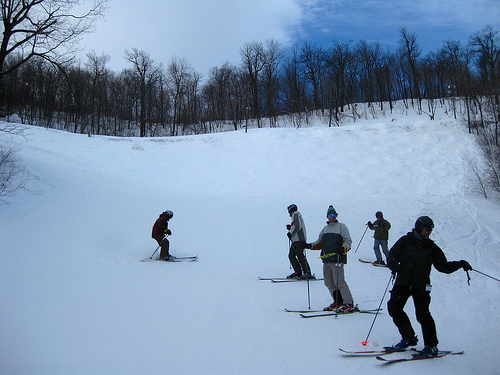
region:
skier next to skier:
[150, 209, 179, 262]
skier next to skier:
[284, 203, 311, 278]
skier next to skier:
[302, 205, 359, 315]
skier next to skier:
[368, 210, 393, 264]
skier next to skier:
[382, 214, 474, 355]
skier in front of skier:
[301, 202, 361, 316]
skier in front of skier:
[377, 215, 469, 357]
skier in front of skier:
[287, 203, 315, 281]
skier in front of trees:
[150, 211, 179, 260]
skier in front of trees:
[286, 204, 314, 283]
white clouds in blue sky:
[118, 2, 152, 40]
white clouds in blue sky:
[245, 11, 290, 46]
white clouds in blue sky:
[287, 9, 347, 41]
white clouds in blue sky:
[174, 21, 205, 51]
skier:
[137, 186, 189, 271]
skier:
[281, 193, 315, 278]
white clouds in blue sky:
[435, 16, 470, 38]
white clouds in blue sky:
[308, 11, 366, 33]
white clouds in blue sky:
[191, 12, 256, 57]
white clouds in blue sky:
[161, 9, 231, 54]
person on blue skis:
[162, 191, 211, 276]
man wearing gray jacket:
[326, 211, 340, 264]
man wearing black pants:
[283, 203, 308, 287]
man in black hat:
[416, 219, 434, 240]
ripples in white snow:
[306, 164, 378, 190]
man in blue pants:
[371, 200, 385, 270]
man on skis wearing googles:
[323, 219, 350, 318]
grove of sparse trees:
[258, 71, 373, 120]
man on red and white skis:
[345, 338, 403, 373]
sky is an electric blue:
[310, 19, 383, 35]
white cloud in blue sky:
[16, 1, 496, 111]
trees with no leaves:
[5, 29, 493, 131]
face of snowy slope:
[5, 125, 474, 367]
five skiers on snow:
[143, 197, 468, 364]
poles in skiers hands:
[363, 260, 498, 348]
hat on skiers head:
[324, 204, 339, 224]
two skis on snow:
[285, 301, 375, 321]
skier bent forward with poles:
[151, 210, 196, 264]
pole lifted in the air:
[443, 257, 498, 285]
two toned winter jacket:
[316, 223, 350, 267]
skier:
[151, 202, 195, 282]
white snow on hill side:
[34, 192, 86, 270]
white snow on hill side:
[170, 292, 205, 323]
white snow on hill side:
[72, 332, 110, 364]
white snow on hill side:
[194, 281, 284, 351]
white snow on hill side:
[340, 133, 408, 177]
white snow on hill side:
[202, 172, 257, 214]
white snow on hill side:
[130, 153, 161, 177]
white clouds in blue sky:
[170, 9, 218, 46]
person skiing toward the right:
[141, 206, 202, 267]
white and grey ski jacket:
[285, 212, 310, 244]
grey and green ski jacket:
[303, 223, 355, 267]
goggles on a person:
[326, 210, 338, 218]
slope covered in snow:
[0, 118, 497, 370]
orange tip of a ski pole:
[361, 338, 370, 346]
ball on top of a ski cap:
[327, 203, 333, 209]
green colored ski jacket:
[371, 218, 391, 240]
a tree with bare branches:
[330, 67, 363, 108]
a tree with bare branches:
[268, 68, 330, 128]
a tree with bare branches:
[241, 81, 266, 111]